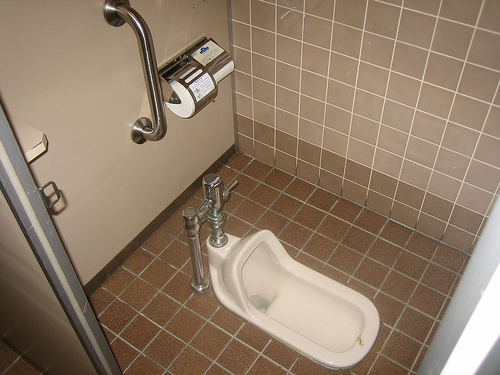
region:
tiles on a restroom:
[109, 267, 161, 312]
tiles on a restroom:
[109, 315, 149, 352]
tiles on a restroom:
[150, 325, 175, 357]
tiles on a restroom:
[185, 340, 220, 367]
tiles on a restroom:
[243, 340, 278, 368]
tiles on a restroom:
[390, 308, 435, 355]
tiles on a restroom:
[367, 263, 424, 298]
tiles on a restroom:
[294, 229, 361, 269]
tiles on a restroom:
[252, 180, 292, 218]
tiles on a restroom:
[215, 135, 263, 175]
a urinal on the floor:
[202, 240, 387, 352]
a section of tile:
[340, 221, 428, 272]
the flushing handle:
[216, 178, 251, 199]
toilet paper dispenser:
[164, 37, 257, 137]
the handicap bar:
[105, 0, 164, 150]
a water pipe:
[174, 213, 209, 293]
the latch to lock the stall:
[35, 167, 92, 233]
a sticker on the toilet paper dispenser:
[184, 67, 214, 102]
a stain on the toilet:
[351, 326, 366, 359]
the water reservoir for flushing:
[243, 284, 282, 316]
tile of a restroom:
[87, 263, 137, 301]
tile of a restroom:
[94, 298, 146, 344]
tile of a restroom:
[163, 295, 213, 350]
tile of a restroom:
[210, 325, 255, 373]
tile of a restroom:
[374, 331, 418, 373]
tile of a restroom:
[375, 278, 414, 310]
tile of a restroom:
[333, 233, 369, 282]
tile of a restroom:
[286, 208, 319, 258]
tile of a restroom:
[247, 175, 279, 216]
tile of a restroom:
[239, 148, 276, 187]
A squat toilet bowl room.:
[151, 161, 398, 367]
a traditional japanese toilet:
[181, 186, 378, 368]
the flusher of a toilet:
[194, 173, 236, 204]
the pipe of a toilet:
[167, 206, 212, 296]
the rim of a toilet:
[247, 222, 298, 269]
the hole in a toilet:
[248, 273, 273, 313]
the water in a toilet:
[248, 289, 306, 321]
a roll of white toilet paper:
[154, 58, 218, 118]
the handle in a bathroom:
[97, 11, 177, 159]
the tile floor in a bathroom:
[124, 281, 179, 356]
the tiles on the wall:
[324, 82, 406, 152]